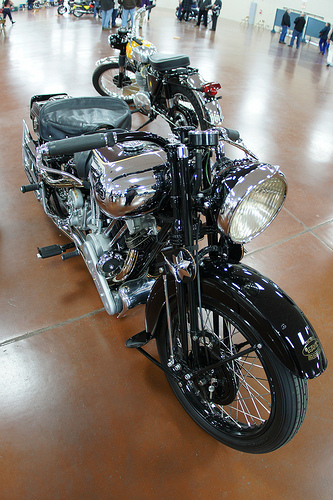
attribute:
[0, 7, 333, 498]
floor — brown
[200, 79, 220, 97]
light — red, tail light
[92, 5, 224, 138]
motorcycles — on display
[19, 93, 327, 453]
motorcycles — on display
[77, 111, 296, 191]
handlebars — gray